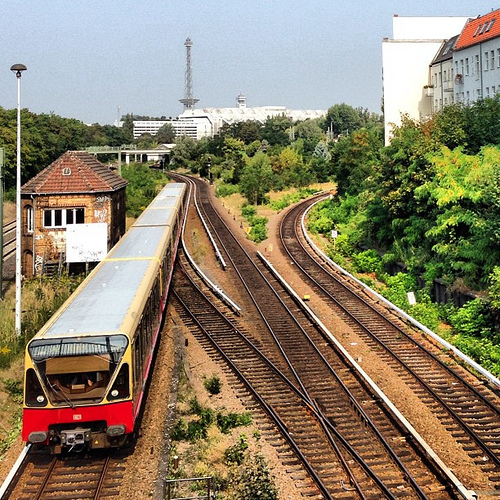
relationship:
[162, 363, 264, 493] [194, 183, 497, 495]
weeds between tracks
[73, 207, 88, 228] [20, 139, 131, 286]
window on building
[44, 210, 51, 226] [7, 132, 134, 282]
window on building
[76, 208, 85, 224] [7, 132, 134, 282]
window on building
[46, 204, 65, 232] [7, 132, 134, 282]
window on building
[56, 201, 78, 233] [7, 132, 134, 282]
window on building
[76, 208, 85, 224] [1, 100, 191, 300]
window on building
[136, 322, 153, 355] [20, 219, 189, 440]
glass window on train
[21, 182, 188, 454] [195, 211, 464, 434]
car on tracks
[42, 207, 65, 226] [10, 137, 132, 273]
window on building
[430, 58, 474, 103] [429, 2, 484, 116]
windows in a building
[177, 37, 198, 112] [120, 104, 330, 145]
tower on top of building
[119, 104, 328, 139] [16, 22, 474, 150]
building in background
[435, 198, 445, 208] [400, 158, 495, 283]
part of bush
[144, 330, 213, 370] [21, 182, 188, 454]
part of car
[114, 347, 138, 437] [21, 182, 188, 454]
side of car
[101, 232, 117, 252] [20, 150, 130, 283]
part of building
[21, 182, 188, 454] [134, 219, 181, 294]
car has car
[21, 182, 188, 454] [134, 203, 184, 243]
car has car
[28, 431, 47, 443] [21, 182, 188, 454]
bumper on car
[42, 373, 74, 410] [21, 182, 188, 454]
wiper on car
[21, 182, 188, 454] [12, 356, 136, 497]
car on tracks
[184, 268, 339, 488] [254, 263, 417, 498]
tracks merging into tracks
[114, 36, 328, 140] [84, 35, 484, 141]
building in background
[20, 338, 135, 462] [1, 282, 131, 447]
front of train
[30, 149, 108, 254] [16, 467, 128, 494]
building next to tracks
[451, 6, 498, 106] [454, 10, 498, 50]
building with roof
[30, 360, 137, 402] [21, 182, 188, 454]
window on car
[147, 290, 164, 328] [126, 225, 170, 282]
window on train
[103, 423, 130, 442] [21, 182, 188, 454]
bumper on car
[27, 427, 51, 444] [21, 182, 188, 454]
bumper on car